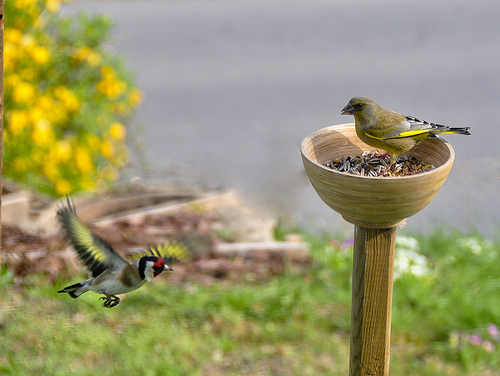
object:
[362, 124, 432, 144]
wing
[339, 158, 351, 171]
seeds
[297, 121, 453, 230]
bowl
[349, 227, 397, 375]
pole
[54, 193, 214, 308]
bird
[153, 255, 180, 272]
beak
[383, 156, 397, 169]
legs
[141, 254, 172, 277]
head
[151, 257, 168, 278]
face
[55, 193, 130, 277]
wingfeathers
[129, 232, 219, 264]
wingfeathers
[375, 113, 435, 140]
wingfeathers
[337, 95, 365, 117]
head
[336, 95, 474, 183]
bird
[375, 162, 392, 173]
feet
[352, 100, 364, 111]
eye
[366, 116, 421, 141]
feathers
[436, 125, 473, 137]
tail